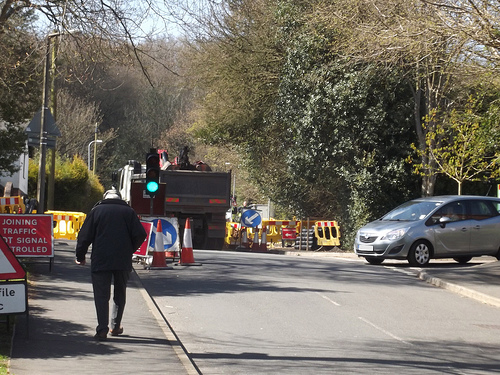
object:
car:
[354, 193, 500, 267]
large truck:
[111, 152, 232, 252]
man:
[74, 189, 148, 341]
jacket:
[74, 198, 147, 273]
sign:
[238, 209, 263, 227]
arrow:
[238, 210, 262, 226]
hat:
[101, 187, 119, 200]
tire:
[406, 238, 434, 267]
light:
[145, 180, 160, 192]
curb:
[419, 264, 500, 310]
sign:
[0, 211, 56, 261]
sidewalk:
[425, 238, 500, 307]